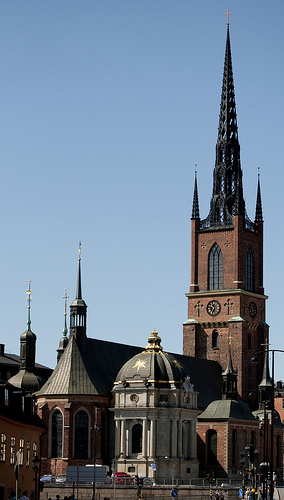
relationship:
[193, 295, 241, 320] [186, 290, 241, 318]
crosses on wall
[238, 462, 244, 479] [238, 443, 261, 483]
part of the light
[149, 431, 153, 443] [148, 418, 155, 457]
part of a pillar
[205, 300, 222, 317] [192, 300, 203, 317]
clock between cross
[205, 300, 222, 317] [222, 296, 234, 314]
clock between cross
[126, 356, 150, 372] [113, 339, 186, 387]
star on roof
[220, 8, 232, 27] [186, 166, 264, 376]
cross on building